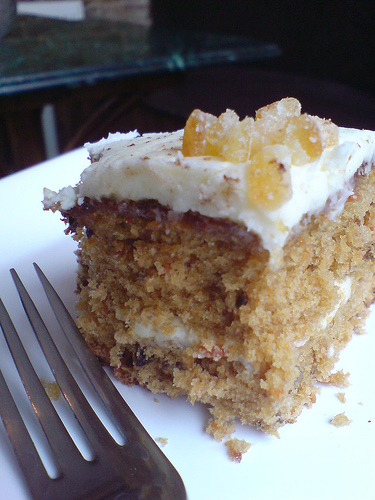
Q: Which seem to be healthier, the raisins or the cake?
A: The raisins are healthier than the cake.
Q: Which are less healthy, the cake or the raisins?
A: The cake are less healthy than the raisins.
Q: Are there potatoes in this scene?
A: Yes, there is a potato.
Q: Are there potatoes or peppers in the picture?
A: Yes, there is a potato.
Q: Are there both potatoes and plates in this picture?
A: Yes, there are both a potato and a plate.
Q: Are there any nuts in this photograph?
A: No, there are no nuts.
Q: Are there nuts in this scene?
A: No, there are no nuts.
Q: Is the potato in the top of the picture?
A: Yes, the potato is in the top of the image.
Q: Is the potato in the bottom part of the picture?
A: No, the potato is in the top of the image.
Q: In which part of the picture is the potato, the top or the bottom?
A: The potato is in the top of the image.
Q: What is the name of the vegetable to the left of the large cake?
A: The vegetable is a potato.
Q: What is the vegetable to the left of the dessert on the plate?
A: The vegetable is a potato.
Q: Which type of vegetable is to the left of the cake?
A: The vegetable is a potato.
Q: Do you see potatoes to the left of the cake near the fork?
A: Yes, there is a potato to the left of the cake.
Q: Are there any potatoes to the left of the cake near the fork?
A: Yes, there is a potato to the left of the cake.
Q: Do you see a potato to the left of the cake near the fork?
A: Yes, there is a potato to the left of the cake.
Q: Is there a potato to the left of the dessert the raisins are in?
A: Yes, there is a potato to the left of the cake.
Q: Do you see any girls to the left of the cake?
A: No, there is a potato to the left of the cake.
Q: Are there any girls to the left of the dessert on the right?
A: No, there is a potato to the left of the cake.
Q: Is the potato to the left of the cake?
A: Yes, the potato is to the left of the cake.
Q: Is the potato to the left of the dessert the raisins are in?
A: Yes, the potato is to the left of the cake.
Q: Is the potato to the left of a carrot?
A: No, the potato is to the left of the cake.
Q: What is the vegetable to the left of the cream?
A: The vegetable is a potato.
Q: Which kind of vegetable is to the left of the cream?
A: The vegetable is a potato.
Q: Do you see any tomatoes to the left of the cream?
A: No, there is a potato to the left of the cream.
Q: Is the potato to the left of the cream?
A: Yes, the potato is to the left of the cream.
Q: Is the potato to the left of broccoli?
A: No, the potato is to the left of the cream.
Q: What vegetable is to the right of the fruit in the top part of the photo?
A: The vegetable is a potato.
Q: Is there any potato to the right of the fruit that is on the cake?
A: Yes, there is a potato to the right of the fruit.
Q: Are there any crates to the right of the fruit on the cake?
A: No, there is a potato to the right of the fruit.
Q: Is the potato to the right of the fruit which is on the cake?
A: Yes, the potato is to the right of the fruit.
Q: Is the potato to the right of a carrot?
A: No, the potato is to the right of the fruit.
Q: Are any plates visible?
A: Yes, there is a plate.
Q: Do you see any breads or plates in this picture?
A: Yes, there is a plate.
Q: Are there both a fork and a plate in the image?
A: Yes, there are both a plate and a fork.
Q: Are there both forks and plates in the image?
A: Yes, there are both a plate and a fork.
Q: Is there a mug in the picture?
A: No, there are no mugs.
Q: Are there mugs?
A: No, there are no mugs.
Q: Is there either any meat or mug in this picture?
A: No, there are no mugs or meat.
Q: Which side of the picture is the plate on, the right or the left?
A: The plate is on the right of the image.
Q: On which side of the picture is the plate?
A: The plate is on the right of the image.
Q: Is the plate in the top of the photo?
A: No, the plate is in the bottom of the image.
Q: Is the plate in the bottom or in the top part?
A: The plate is in the bottom of the image.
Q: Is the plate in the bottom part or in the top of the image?
A: The plate is in the bottom of the image.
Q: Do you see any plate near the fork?
A: Yes, there is a plate near the fork.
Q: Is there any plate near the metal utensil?
A: Yes, there is a plate near the fork.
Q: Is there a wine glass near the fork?
A: No, there is a plate near the fork.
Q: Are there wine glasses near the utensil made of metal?
A: No, there is a plate near the fork.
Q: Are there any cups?
A: No, there are no cups.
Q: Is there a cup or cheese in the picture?
A: No, there are no cups or cheese.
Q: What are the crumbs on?
A: The crumbs are on the plate.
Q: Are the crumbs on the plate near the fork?
A: Yes, the crumbs are on the plate.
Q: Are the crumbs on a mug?
A: No, the crumbs are on the plate.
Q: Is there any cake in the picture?
A: Yes, there is a cake.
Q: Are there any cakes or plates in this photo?
A: Yes, there is a cake.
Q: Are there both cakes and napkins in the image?
A: No, there is a cake but no napkins.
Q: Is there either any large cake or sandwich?
A: Yes, there is a large cake.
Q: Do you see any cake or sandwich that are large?
A: Yes, the cake is large.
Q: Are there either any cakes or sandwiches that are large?
A: Yes, the cake is large.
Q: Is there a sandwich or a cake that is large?
A: Yes, the cake is large.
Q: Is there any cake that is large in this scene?
A: Yes, there is a large cake.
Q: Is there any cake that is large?
A: Yes, there is a cake that is large.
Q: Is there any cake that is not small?
A: Yes, there is a large cake.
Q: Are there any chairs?
A: No, there are no chairs.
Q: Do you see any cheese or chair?
A: No, there are no chairs or cheese.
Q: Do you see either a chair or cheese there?
A: No, there are no chairs or cheese.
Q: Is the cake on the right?
A: Yes, the cake is on the right of the image.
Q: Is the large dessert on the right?
A: Yes, the cake is on the right of the image.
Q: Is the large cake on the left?
A: No, the cake is on the right of the image.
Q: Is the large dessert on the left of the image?
A: No, the cake is on the right of the image.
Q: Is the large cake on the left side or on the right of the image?
A: The cake is on the right of the image.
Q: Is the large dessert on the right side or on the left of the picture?
A: The cake is on the right of the image.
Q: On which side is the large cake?
A: The cake is on the right of the image.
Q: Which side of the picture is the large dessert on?
A: The cake is on the right of the image.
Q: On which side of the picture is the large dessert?
A: The cake is on the right of the image.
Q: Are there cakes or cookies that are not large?
A: No, there is a cake but it is large.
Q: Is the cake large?
A: Yes, the cake is large.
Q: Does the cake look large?
A: Yes, the cake is large.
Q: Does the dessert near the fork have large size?
A: Yes, the cake is large.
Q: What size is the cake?
A: The cake is large.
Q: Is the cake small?
A: No, the cake is large.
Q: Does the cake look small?
A: No, the cake is large.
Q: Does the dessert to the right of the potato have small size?
A: No, the cake is large.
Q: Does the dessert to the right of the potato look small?
A: No, the cake is large.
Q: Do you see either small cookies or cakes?
A: No, there is a cake but it is large.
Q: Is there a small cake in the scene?
A: No, there is a cake but it is large.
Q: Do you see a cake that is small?
A: No, there is a cake but it is large.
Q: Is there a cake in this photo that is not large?
A: No, there is a cake but it is large.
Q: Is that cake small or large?
A: The cake is large.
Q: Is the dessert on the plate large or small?
A: The cake is large.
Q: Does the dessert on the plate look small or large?
A: The cake is large.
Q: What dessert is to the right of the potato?
A: The dessert is a cake.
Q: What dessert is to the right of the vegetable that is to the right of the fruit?
A: The dessert is a cake.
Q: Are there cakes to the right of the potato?
A: Yes, there is a cake to the right of the potato.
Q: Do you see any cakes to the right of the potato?
A: Yes, there is a cake to the right of the potato.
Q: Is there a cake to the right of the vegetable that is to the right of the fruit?
A: Yes, there is a cake to the right of the potato.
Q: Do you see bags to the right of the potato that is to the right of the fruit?
A: No, there is a cake to the right of the potato.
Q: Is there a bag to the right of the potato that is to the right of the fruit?
A: No, there is a cake to the right of the potato.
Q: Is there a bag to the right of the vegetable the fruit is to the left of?
A: No, there is a cake to the right of the potato.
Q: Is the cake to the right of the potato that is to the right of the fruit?
A: Yes, the cake is to the right of the potato.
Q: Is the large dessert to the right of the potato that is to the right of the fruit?
A: Yes, the cake is to the right of the potato.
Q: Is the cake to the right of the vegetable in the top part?
A: Yes, the cake is to the right of the potato.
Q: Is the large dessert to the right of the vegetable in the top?
A: Yes, the cake is to the right of the potato.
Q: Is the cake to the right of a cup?
A: No, the cake is to the right of the potato.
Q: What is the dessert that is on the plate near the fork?
A: The dessert is a cake.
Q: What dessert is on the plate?
A: The dessert is a cake.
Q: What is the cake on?
A: The cake is on the plate.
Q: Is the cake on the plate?
A: Yes, the cake is on the plate.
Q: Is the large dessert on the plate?
A: Yes, the cake is on the plate.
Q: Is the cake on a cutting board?
A: No, the cake is on the plate.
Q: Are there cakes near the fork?
A: Yes, there is a cake near the fork.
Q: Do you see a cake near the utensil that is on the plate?
A: Yes, there is a cake near the fork.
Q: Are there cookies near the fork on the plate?
A: No, there is a cake near the fork.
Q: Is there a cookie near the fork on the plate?
A: No, there is a cake near the fork.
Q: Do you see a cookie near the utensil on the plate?
A: No, there is a cake near the fork.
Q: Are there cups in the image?
A: No, there are no cups.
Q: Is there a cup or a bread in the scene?
A: No, there are no cups or breads.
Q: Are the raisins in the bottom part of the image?
A: Yes, the raisins are in the bottom of the image.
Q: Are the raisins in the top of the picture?
A: No, the raisins are in the bottom of the image.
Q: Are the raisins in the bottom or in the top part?
A: The raisins are in the bottom of the image.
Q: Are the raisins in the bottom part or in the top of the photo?
A: The raisins are in the bottom of the image.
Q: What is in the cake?
A: The raisins are in the cake.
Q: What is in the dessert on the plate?
A: The raisins are in the cake.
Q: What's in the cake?
A: The raisins are in the cake.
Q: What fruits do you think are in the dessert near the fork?
A: The fruits are raisins.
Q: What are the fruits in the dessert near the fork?
A: The fruits are raisins.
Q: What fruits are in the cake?
A: The fruits are raisins.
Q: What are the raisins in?
A: The raisins are in the cake.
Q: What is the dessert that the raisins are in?
A: The dessert is a cake.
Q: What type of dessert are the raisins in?
A: The raisins are in the cake.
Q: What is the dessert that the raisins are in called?
A: The dessert is a cake.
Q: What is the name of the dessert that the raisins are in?
A: The dessert is a cake.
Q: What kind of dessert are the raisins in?
A: The raisins are in the cake.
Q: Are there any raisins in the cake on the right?
A: Yes, there are raisins in the cake.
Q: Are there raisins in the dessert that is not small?
A: Yes, there are raisins in the cake.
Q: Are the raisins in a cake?
A: Yes, the raisins are in a cake.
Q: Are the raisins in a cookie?
A: No, the raisins are in a cake.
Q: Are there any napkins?
A: No, there are no napkins.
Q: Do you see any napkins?
A: No, there are no napkins.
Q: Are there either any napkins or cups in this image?
A: No, there are no napkins or cups.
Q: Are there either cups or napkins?
A: No, there are no napkins or cups.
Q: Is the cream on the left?
A: No, the cream is on the right of the image.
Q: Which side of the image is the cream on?
A: The cream is on the right of the image.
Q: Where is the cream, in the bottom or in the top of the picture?
A: The cream is in the top of the image.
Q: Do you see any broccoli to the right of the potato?
A: No, there is cream to the right of the potato.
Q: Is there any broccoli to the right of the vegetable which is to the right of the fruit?
A: No, there is cream to the right of the potato.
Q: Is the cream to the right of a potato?
A: Yes, the cream is to the right of a potato.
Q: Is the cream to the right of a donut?
A: No, the cream is to the right of a potato.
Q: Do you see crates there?
A: No, there are no crates.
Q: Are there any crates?
A: No, there are no crates.